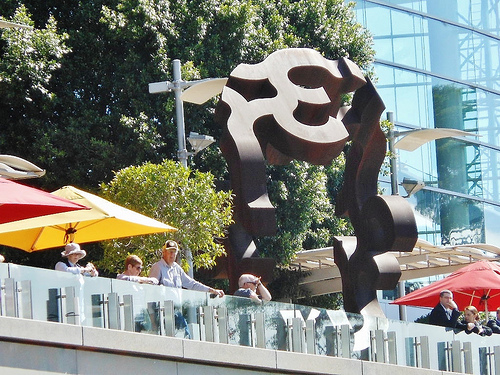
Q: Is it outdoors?
A: Yes, it is outdoors.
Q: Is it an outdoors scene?
A: Yes, it is outdoors.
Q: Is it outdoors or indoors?
A: It is outdoors.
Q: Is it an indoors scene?
A: No, it is outdoors.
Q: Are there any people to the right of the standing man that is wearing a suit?
A: Yes, there is a person to the right of the man.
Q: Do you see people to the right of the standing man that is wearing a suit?
A: Yes, there is a person to the right of the man.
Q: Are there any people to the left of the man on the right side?
A: No, the person is to the right of the man.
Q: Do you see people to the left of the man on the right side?
A: No, the person is to the right of the man.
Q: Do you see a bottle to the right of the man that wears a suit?
A: No, there is a person to the right of the man.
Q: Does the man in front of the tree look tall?
A: Yes, the man is tall.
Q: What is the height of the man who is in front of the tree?
A: The man is tall.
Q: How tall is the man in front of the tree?
A: The man is tall.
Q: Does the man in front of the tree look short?
A: No, the man is tall.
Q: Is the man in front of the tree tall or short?
A: The man is tall.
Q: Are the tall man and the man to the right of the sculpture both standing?
A: Yes, both the man and the man are standing.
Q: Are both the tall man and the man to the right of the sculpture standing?
A: Yes, both the man and the man are standing.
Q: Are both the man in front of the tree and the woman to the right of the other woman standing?
A: Yes, both the man and the woman are standing.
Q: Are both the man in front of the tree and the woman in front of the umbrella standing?
A: Yes, both the man and the woman are standing.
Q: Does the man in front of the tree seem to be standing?
A: Yes, the man is standing.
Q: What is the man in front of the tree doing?
A: The man is standing.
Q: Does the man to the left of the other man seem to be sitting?
A: No, the man is standing.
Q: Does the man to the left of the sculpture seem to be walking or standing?
A: The man is standing.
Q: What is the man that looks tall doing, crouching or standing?
A: The man is standing.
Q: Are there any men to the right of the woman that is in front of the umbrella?
A: Yes, there is a man to the right of the woman.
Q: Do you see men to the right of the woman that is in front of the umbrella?
A: Yes, there is a man to the right of the woman.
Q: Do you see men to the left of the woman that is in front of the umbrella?
A: No, the man is to the right of the woman.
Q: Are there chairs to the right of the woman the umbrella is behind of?
A: No, there is a man to the right of the woman.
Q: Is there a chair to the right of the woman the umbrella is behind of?
A: No, there is a man to the right of the woman.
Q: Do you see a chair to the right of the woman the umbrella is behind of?
A: No, there is a man to the right of the woman.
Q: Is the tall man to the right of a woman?
A: Yes, the man is to the right of a woman.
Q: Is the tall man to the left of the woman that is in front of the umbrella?
A: No, the man is to the right of the woman.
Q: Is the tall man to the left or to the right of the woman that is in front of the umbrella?
A: The man is to the right of the woman.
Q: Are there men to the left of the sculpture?
A: Yes, there is a man to the left of the sculpture.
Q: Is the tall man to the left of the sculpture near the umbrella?
A: Yes, the man is to the left of the sculpture.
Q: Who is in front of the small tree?
A: The man is in front of the tree.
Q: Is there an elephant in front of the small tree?
A: No, there is a man in front of the tree.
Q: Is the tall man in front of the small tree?
A: Yes, the man is in front of the tree.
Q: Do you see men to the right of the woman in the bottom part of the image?
A: Yes, there is a man to the right of the woman.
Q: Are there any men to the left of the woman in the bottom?
A: No, the man is to the right of the woman.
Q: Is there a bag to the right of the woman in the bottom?
A: No, there is a man to the right of the woman.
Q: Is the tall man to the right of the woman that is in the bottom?
A: Yes, the man is to the right of the woman.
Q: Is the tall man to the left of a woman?
A: No, the man is to the right of a woman.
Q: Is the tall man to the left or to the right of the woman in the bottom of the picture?
A: The man is to the right of the woman.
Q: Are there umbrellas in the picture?
A: Yes, there is an umbrella.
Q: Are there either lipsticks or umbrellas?
A: Yes, there is an umbrella.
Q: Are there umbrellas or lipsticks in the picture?
A: Yes, there is an umbrella.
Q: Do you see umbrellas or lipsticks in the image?
A: Yes, there is an umbrella.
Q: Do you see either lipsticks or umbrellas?
A: Yes, there is an umbrella.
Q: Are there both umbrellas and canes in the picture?
A: No, there is an umbrella but no canes.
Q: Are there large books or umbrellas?
A: Yes, there is a large umbrella.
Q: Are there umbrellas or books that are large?
A: Yes, the umbrella is large.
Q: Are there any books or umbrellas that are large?
A: Yes, the umbrella is large.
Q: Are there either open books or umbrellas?
A: Yes, there is an open umbrella.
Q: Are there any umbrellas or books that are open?
A: Yes, the umbrella is open.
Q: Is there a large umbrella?
A: Yes, there is a large umbrella.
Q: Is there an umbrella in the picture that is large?
A: Yes, there is an umbrella that is large.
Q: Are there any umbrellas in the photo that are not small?
A: Yes, there is a large umbrella.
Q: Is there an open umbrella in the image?
A: Yes, there is an open umbrella.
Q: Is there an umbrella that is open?
A: Yes, there is an umbrella that is open.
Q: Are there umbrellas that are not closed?
A: Yes, there is a open umbrella.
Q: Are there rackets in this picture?
A: No, there are no rackets.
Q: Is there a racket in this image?
A: No, there are no rackets.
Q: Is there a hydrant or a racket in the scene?
A: No, there are no rackets or fire hydrants.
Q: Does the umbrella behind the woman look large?
A: Yes, the umbrella is large.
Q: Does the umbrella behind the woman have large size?
A: Yes, the umbrella is large.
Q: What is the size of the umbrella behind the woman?
A: The umbrella is large.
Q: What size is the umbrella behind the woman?
A: The umbrella is large.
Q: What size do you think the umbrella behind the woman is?
A: The umbrella is large.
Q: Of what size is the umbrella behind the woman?
A: The umbrella is large.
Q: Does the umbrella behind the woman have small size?
A: No, the umbrella is large.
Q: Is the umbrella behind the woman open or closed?
A: The umbrella is open.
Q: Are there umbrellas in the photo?
A: Yes, there is an umbrella.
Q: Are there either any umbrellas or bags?
A: Yes, there is an umbrella.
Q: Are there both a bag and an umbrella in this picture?
A: No, there is an umbrella but no bags.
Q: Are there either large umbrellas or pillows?
A: Yes, there is a large umbrella.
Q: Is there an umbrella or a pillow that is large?
A: Yes, the umbrella is large.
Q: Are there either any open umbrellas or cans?
A: Yes, there is an open umbrella.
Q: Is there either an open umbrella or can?
A: Yes, there is an open umbrella.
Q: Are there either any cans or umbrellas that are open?
A: Yes, the umbrella is open.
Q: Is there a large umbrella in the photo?
A: Yes, there is a large umbrella.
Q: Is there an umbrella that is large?
A: Yes, there is an umbrella that is large.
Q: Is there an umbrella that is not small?
A: Yes, there is a large umbrella.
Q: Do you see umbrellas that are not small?
A: Yes, there is a large umbrella.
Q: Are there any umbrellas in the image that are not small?
A: Yes, there is a large umbrella.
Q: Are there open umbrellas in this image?
A: Yes, there is an open umbrella.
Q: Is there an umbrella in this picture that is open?
A: Yes, there is an open umbrella.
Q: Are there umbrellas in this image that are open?
A: Yes, there is an umbrella that is open.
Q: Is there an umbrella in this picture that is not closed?
A: Yes, there is a open umbrella.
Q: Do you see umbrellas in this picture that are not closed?
A: Yes, there is a open umbrella.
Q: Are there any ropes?
A: No, there are no ropes.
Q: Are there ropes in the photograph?
A: No, there are no ropes.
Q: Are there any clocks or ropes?
A: No, there are no ropes or clocks.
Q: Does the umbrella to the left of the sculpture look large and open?
A: Yes, the umbrella is large and open.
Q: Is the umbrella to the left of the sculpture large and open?
A: Yes, the umbrella is large and open.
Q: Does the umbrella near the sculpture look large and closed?
A: No, the umbrella is large but open.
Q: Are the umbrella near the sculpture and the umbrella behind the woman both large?
A: Yes, both the umbrella and the umbrella are large.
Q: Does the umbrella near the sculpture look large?
A: Yes, the umbrella is large.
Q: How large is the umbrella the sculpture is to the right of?
A: The umbrella is large.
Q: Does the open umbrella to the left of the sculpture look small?
A: No, the umbrella is large.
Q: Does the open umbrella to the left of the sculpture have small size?
A: No, the umbrella is large.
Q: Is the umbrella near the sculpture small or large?
A: The umbrella is large.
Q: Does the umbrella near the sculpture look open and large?
A: Yes, the umbrella is open and large.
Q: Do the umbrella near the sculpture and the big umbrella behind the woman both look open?
A: Yes, both the umbrella and the umbrella are open.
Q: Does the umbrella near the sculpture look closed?
A: No, the umbrella is open.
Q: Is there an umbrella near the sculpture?
A: Yes, there is an umbrella near the sculpture.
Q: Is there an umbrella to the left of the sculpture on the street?
A: Yes, there is an umbrella to the left of the sculpture.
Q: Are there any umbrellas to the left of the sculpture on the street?
A: Yes, there is an umbrella to the left of the sculpture.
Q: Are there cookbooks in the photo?
A: No, there are no cookbooks.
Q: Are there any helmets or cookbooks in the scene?
A: No, there are no cookbooks or helmets.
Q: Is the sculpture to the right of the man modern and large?
A: Yes, the sculpture is modern and large.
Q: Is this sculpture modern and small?
A: No, the sculpture is modern but large.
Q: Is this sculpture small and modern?
A: No, the sculpture is modern but large.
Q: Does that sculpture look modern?
A: Yes, the sculpture is modern.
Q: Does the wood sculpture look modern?
A: Yes, the sculpture is modern.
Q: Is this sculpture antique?
A: No, the sculpture is modern.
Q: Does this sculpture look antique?
A: No, the sculpture is modern.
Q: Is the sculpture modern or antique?
A: The sculpture is modern.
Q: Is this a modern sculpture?
A: Yes, this is a modern sculpture.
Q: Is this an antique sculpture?
A: No, this is a modern sculpture.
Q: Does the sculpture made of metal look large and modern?
A: Yes, the sculpture is large and modern.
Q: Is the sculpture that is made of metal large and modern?
A: Yes, the sculpture is large and modern.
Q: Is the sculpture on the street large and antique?
A: No, the sculpture is large but modern.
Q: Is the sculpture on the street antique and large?
A: No, the sculpture is large but modern.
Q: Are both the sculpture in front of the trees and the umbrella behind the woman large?
A: Yes, both the sculpture and the umbrella are large.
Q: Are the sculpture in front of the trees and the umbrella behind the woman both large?
A: Yes, both the sculpture and the umbrella are large.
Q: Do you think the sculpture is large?
A: Yes, the sculpture is large.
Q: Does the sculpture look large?
A: Yes, the sculpture is large.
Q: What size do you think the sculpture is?
A: The sculpture is large.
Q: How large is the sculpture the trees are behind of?
A: The sculpture is large.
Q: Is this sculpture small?
A: No, the sculpture is large.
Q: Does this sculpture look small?
A: No, the sculpture is large.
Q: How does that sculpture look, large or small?
A: The sculpture is large.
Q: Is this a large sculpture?
A: Yes, this is a large sculpture.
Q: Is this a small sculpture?
A: No, this is a large sculpture.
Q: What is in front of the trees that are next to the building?
A: The sculpture is in front of the trees.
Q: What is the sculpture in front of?
A: The sculpture is in front of the trees.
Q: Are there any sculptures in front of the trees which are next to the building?
A: Yes, there is a sculpture in front of the trees.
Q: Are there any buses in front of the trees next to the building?
A: No, there is a sculpture in front of the trees.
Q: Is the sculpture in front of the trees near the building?
A: Yes, the sculpture is in front of the trees.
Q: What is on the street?
A: The sculpture is on the street.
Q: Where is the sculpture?
A: The sculpture is on the street.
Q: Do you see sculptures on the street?
A: Yes, there is a sculpture on the street.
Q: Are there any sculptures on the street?
A: Yes, there is a sculpture on the street.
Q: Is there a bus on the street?
A: No, there is a sculpture on the street.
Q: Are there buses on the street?
A: No, there is a sculpture on the street.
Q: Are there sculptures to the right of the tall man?
A: Yes, there is a sculpture to the right of the man.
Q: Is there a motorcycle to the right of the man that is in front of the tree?
A: No, there is a sculpture to the right of the man.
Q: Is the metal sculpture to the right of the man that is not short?
A: Yes, the sculpture is to the right of the man.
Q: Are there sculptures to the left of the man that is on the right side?
A: Yes, there is a sculpture to the left of the man.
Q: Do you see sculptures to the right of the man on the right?
A: No, the sculpture is to the left of the man.